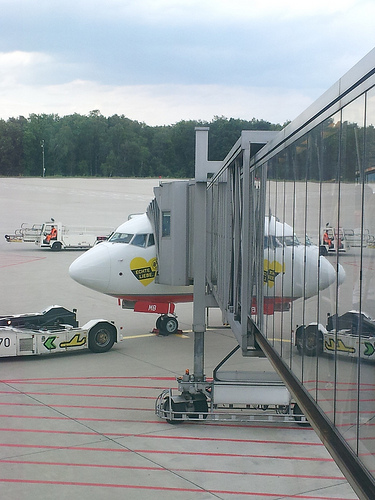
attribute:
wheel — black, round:
[87, 318, 120, 352]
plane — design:
[66, 203, 198, 339]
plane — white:
[69, 209, 191, 335]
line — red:
[236, 140, 290, 363]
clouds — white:
[21, 66, 86, 98]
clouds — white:
[21, 17, 321, 105]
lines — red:
[0, 375, 374, 498]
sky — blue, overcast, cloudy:
[1, 2, 374, 135]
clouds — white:
[21, 6, 342, 98]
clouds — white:
[0, 0, 374, 129]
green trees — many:
[22, 123, 163, 164]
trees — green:
[10, 117, 65, 163]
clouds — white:
[6, 63, 282, 126]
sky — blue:
[29, 17, 357, 98]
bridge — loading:
[143, 139, 374, 399]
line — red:
[2, 476, 353, 498]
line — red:
[3, 457, 345, 480]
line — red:
[2, 440, 334, 462]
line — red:
[3, 426, 324, 447]